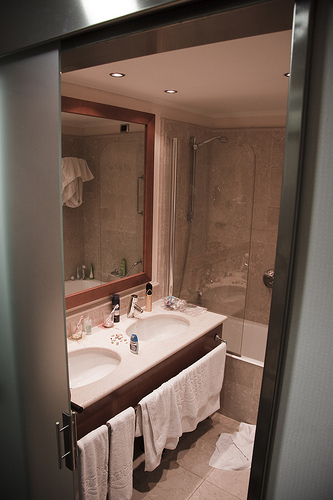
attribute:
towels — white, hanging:
[83, 389, 180, 466]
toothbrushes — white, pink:
[170, 269, 178, 309]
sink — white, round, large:
[126, 318, 210, 343]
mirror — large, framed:
[69, 103, 158, 295]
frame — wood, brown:
[141, 116, 157, 284]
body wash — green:
[109, 253, 133, 276]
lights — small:
[111, 72, 193, 109]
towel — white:
[63, 162, 92, 202]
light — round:
[105, 70, 141, 86]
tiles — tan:
[159, 446, 227, 497]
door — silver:
[23, 398, 79, 476]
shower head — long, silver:
[192, 134, 230, 146]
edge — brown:
[59, 94, 164, 123]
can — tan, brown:
[135, 280, 153, 318]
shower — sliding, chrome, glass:
[174, 136, 277, 356]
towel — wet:
[210, 421, 286, 485]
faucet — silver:
[99, 300, 145, 316]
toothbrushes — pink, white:
[76, 312, 88, 329]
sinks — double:
[66, 300, 216, 375]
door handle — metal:
[39, 410, 81, 474]